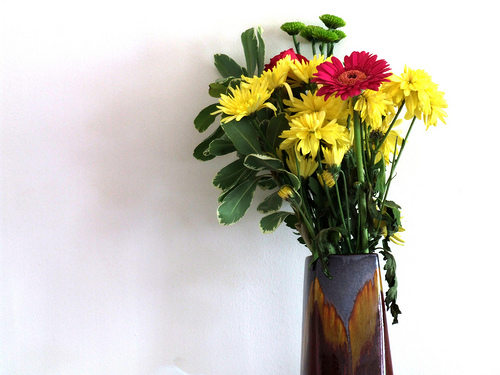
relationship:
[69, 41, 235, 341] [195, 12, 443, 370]
shadow of flowers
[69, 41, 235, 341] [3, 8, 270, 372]
shadow on wall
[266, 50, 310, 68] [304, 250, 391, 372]
flower in vase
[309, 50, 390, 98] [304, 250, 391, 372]
daisy in vase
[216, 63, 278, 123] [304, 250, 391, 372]
daisies in vase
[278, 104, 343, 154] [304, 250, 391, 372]
daisies in vase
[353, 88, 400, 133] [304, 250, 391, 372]
flower in vase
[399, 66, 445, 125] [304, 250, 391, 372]
daisies in vase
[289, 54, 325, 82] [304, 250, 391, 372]
flower in vase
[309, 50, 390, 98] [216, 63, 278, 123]
daisy with daisies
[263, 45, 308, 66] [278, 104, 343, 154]
flower with daisies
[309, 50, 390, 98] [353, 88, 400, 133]
daisy with flower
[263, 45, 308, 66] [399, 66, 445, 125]
flower with daisies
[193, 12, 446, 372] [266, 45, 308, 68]
bouquet of flower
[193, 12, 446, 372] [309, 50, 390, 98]
bouquet of daisy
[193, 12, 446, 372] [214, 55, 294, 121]
bouquet of flower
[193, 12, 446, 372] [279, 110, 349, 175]
bouquet of flower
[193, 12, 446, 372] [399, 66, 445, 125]
bouquet of daisies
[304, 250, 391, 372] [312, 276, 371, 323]
vase with painting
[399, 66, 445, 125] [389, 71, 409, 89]
daisies with petals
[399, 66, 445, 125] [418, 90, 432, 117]
daisies with petals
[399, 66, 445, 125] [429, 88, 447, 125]
daisies with petals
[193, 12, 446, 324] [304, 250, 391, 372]
bouquet in a vase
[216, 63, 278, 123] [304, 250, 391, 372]
daisies in a vase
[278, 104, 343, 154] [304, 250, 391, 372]
daisies in a vase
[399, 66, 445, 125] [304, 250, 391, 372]
daisies in a vase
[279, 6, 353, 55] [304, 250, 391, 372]
flowers in a vase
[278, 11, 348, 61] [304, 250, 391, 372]
flowers in a vase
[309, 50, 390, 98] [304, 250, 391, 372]
daisy in a vase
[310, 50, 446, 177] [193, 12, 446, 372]
flowers hanging from a bouquet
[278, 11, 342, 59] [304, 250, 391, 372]
flowers in a vase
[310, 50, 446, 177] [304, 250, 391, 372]
flowers in a vase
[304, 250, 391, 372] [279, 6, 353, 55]
vase with flowers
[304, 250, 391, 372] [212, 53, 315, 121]
vase with flowers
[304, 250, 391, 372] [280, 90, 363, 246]
vase with flowers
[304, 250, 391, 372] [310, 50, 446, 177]
vase with flowers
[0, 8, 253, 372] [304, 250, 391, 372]
wall behind vase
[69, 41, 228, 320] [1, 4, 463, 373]
shadow on a wall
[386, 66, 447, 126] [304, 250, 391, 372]
flower in vase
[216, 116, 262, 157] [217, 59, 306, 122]
leaves of flowers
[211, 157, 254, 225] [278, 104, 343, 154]
leaves of daisies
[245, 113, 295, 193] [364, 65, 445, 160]
leaves of flowers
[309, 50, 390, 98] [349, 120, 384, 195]
daisy on stems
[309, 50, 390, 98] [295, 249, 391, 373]
daisy in vase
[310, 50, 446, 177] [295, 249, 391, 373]
flowers in vase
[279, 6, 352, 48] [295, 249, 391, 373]
flowers are in vase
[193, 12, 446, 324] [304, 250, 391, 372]
bouquet in vase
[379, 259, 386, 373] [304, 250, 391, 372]
light reflecting on vase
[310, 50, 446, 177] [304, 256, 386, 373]
flowers hanging over vase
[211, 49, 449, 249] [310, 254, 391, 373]
daisies in vase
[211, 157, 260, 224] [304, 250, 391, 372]
leaves in vase